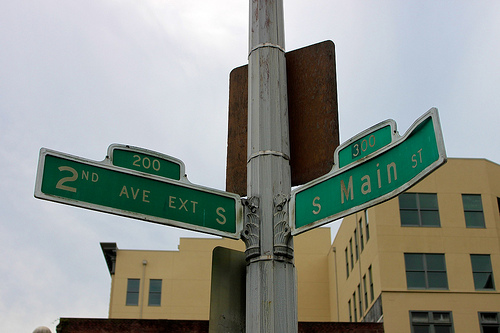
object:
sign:
[30, 140, 242, 241]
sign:
[288, 105, 447, 238]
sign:
[104, 142, 186, 183]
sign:
[329, 117, 397, 172]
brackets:
[271, 193, 294, 259]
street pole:
[242, 0, 297, 333]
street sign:
[222, 38, 343, 199]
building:
[53, 156, 500, 332]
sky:
[0, 0, 497, 333]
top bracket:
[247, 43, 286, 58]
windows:
[146, 278, 164, 307]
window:
[458, 192, 488, 230]